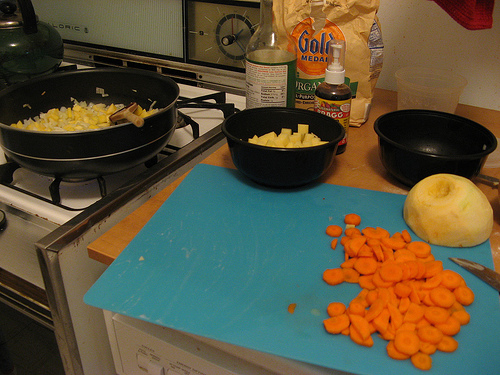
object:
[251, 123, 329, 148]
cheese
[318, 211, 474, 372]
food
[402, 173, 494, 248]
potato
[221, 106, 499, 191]
bowls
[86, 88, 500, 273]
counter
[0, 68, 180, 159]
pot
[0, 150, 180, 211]
stove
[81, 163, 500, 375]
mat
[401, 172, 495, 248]
parsnip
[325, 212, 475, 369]
carrots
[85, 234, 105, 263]
corner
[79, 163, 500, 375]
pad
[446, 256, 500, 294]
knife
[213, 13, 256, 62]
dial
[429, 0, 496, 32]
towel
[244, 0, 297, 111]
container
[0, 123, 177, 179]
pan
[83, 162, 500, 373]
board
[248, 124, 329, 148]
potatoes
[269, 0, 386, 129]
flour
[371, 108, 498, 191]
bowl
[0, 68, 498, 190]
pots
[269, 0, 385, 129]
packet